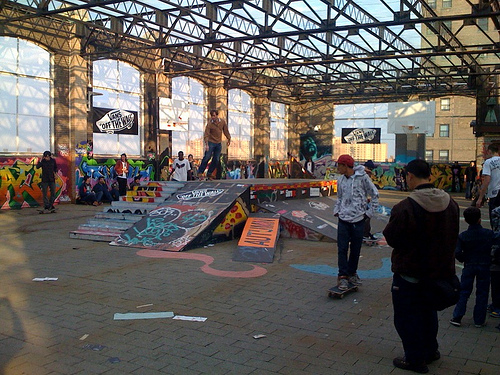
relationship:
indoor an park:
[5, 24, 495, 333] [23, 180, 471, 301]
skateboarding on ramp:
[180, 109, 326, 183] [111, 182, 257, 259]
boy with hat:
[322, 153, 380, 302] [328, 151, 361, 168]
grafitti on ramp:
[170, 185, 231, 202] [111, 182, 257, 259]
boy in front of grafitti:
[322, 153, 380, 302] [170, 185, 231, 202]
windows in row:
[0, 30, 295, 162] [0, 26, 298, 160]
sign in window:
[86, 105, 145, 135] [88, 50, 151, 164]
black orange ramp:
[269, 189, 398, 246] [111, 182, 257, 259]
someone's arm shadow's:
[33, 150, 68, 212] [59, 160, 78, 202]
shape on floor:
[130, 247, 268, 281] [0, 196, 499, 312]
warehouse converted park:
[0, 0, 499, 373] [69, 175, 401, 267]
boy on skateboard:
[322, 153, 380, 302] [327, 275, 362, 296]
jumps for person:
[70, 180, 182, 237] [196, 111, 232, 181]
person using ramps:
[196, 111, 232, 181] [80, 177, 397, 250]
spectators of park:
[372, 142, 499, 368] [69, 175, 401, 267]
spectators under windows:
[31, 148, 207, 210] [0, 30, 295, 162]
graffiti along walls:
[1, 159, 298, 206] [3, 152, 485, 210]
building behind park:
[415, 2, 500, 170] [69, 175, 401, 267]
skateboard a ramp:
[327, 275, 362, 296] [111, 182, 257, 259]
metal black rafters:
[6, 3, 184, 50] [1, 1, 499, 88]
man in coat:
[32, 150, 64, 213] [32, 157, 61, 177]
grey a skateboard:
[321, 278, 363, 299] [327, 275, 362, 296]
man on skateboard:
[32, 150, 64, 213] [327, 275, 362, 296]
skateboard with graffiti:
[327, 275, 362, 296] [1, 159, 298, 206]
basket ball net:
[385, 100, 435, 136] [402, 126, 421, 138]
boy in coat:
[322, 153, 380, 302] [32, 157, 61, 177]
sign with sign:
[86, 105, 145, 135] [86, 105, 145, 135]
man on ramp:
[32, 150, 64, 213] [111, 182, 257, 259]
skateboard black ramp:
[327, 275, 362, 296] [111, 182, 257, 259]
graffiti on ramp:
[1, 159, 298, 206] [111, 182, 257, 259]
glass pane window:
[172, 77, 203, 156] [88, 50, 151, 164]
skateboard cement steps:
[327, 275, 362, 296] [69, 175, 191, 240]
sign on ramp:
[239, 213, 281, 251] [111, 182, 257, 259]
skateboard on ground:
[327, 275, 362, 296] [0, 175, 498, 369]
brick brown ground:
[199, 345, 215, 357] [0, 175, 498, 369]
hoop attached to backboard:
[401, 123, 418, 131] [383, 99, 436, 135]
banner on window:
[155, 94, 193, 133] [88, 50, 151, 164]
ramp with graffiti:
[111, 182, 257, 259] [1, 159, 298, 206]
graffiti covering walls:
[1, 159, 298, 206] [3, 152, 485, 210]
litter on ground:
[36, 273, 265, 345] [0, 175, 498, 369]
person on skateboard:
[196, 111, 231, 175] [327, 275, 362, 296]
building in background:
[415, 2, 494, 169] [330, 90, 500, 160]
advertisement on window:
[89, 103, 145, 134] [88, 50, 151, 164]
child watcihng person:
[455, 204, 492, 325] [196, 111, 232, 181]